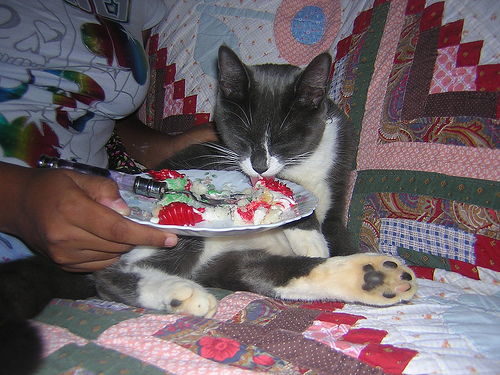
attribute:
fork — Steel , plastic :
[34, 155, 246, 207]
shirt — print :
[1, 1, 168, 261]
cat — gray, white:
[202, 48, 353, 208]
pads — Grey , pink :
[360, 252, 415, 304]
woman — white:
[0, 0, 219, 321]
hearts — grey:
[9, 17, 70, 56]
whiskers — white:
[203, 137, 260, 174]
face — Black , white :
[213, 47, 333, 179]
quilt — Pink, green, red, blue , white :
[18, 7, 490, 373]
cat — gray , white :
[14, 42, 449, 330]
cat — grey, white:
[97, 43, 420, 323]